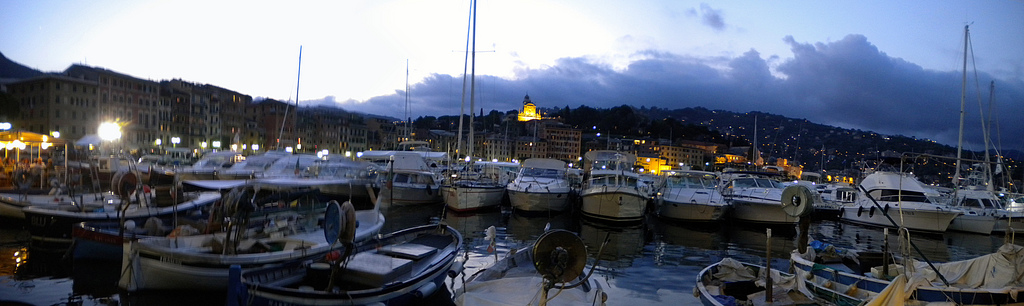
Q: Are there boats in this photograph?
A: Yes, there is a boat.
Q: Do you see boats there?
A: Yes, there is a boat.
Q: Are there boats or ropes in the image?
A: Yes, there is a boat.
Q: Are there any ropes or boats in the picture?
A: Yes, there is a boat.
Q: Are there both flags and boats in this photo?
A: No, there is a boat but no flags.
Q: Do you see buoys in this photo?
A: No, there are no buoys.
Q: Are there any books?
A: No, there are no books.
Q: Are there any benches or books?
A: No, there are no books or benches.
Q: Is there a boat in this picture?
A: Yes, there is a boat.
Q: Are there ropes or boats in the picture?
A: Yes, there is a boat.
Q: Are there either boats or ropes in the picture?
A: Yes, there is a boat.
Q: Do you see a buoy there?
A: No, there are no buoys.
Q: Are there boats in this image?
A: Yes, there is a boat.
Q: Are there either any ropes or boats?
A: Yes, there is a boat.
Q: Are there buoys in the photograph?
A: No, there are no buoys.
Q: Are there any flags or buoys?
A: No, there are no buoys or flags.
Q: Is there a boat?
A: Yes, there is a boat.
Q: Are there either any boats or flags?
A: Yes, there is a boat.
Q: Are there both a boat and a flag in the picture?
A: No, there is a boat but no flags.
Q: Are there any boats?
A: Yes, there is a boat.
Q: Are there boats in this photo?
A: Yes, there is a boat.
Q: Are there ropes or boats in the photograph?
A: Yes, there is a boat.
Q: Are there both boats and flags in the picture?
A: No, there is a boat but no flags.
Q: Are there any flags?
A: No, there are no flags.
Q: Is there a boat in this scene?
A: Yes, there is a boat.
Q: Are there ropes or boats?
A: Yes, there is a boat.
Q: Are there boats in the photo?
A: Yes, there is a boat.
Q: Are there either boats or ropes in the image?
A: Yes, there is a boat.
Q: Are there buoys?
A: No, there are no buoys.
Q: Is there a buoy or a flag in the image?
A: No, there are no buoys or flags.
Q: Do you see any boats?
A: Yes, there is a boat.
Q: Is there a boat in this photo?
A: Yes, there is a boat.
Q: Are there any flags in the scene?
A: No, there are no flags.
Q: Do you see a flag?
A: No, there are no flags.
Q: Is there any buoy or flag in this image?
A: No, there are no flags or buoys.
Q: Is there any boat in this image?
A: Yes, there is a boat.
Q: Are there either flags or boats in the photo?
A: Yes, there is a boat.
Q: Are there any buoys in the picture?
A: No, there are no buoys.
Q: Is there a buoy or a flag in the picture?
A: No, there are no buoys or flags.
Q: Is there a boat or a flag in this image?
A: Yes, there is a boat.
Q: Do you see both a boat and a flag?
A: No, there is a boat but no flags.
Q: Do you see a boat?
A: Yes, there is a boat.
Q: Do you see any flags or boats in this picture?
A: Yes, there is a boat.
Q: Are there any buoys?
A: No, there are no buoys.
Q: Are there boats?
A: Yes, there is a boat.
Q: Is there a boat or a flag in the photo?
A: Yes, there is a boat.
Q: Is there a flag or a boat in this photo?
A: Yes, there is a boat.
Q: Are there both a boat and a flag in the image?
A: No, there is a boat but no flags.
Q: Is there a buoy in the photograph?
A: No, there are no buoys.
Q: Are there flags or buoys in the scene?
A: No, there are no buoys or flags.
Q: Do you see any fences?
A: No, there are no fences.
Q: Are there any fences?
A: No, there are no fences.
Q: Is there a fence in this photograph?
A: No, there are no fences.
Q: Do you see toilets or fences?
A: No, there are no fences or toilets.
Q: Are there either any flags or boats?
A: Yes, there is a boat.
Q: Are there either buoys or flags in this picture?
A: No, there are no buoys or flags.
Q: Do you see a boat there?
A: Yes, there is a boat.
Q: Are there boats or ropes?
A: Yes, there is a boat.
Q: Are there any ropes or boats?
A: Yes, there is a boat.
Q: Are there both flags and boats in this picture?
A: No, there is a boat but no flags.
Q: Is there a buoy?
A: No, there are no buoys.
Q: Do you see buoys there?
A: No, there are no buoys.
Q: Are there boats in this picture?
A: Yes, there is a boat.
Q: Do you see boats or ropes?
A: Yes, there is a boat.